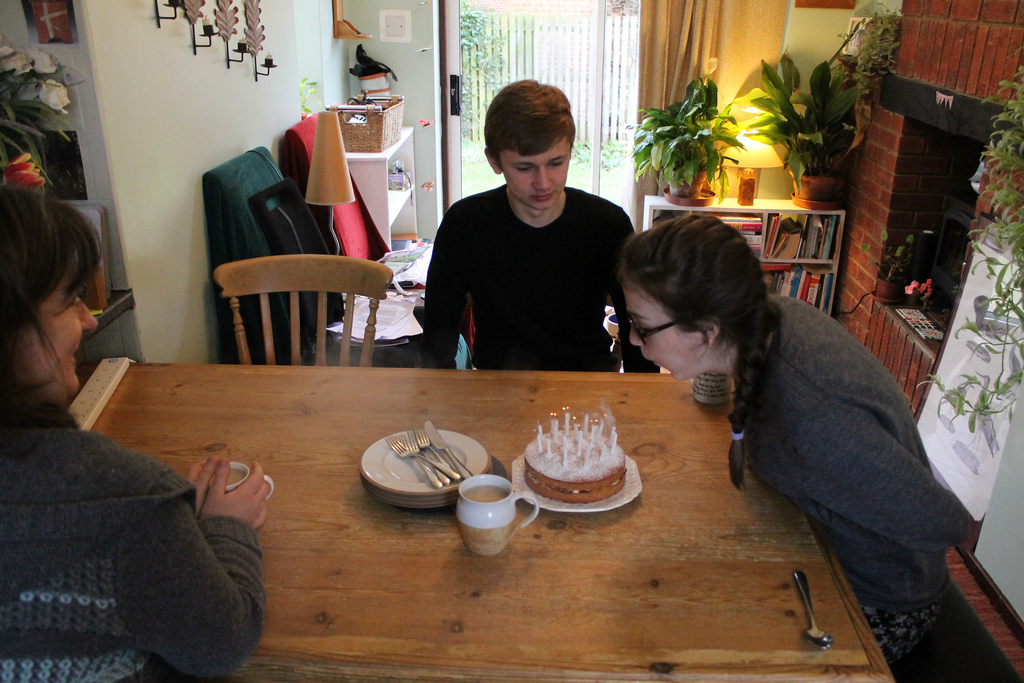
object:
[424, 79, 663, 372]
boy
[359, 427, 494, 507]
plates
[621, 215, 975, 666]
girl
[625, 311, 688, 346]
glasses